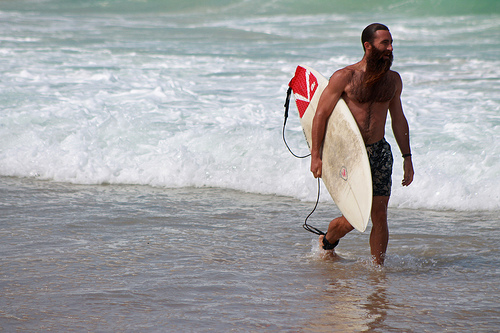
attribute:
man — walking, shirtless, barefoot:
[311, 23, 416, 267]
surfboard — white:
[290, 62, 373, 234]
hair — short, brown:
[361, 22, 389, 52]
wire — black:
[281, 90, 288, 141]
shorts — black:
[366, 137, 394, 198]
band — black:
[401, 152, 411, 157]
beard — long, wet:
[365, 45, 395, 89]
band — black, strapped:
[321, 232, 339, 251]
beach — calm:
[1, 176, 499, 333]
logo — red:
[290, 66, 319, 116]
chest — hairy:
[346, 75, 395, 105]